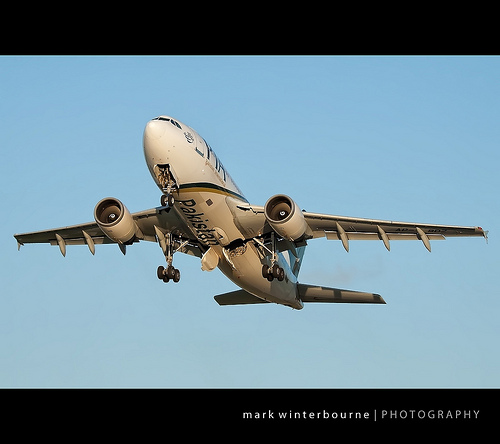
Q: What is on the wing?
A: Jet engine.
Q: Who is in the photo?
A: No people.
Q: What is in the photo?
A: A plane.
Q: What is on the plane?
A: Writing.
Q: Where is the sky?
A: Above the plane.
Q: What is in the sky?
A: A plane.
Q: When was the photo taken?
A: In the daytime.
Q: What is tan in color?
A: Plane.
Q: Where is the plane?
A: In the air.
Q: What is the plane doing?
A: Flying.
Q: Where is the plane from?
A: Pakistan.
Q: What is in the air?
A: Plane.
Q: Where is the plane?
A: In the sky.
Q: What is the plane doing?
A: Flying.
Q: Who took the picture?
A: Mark Winterbourne.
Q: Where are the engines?
A: On the wings.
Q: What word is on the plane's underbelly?
A: Pakistan.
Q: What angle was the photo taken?
A: From below.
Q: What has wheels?
A: The plane's landing gear.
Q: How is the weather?
A: Clear.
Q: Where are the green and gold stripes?
A: On the plane's body.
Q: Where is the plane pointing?
A: Up.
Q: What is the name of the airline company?
A: Pakistan.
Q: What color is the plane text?
A: Blue.